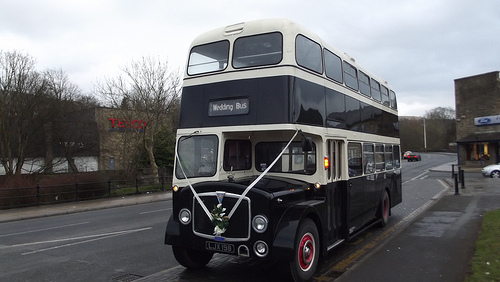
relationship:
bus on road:
[165, 17, 403, 281] [1, 151, 458, 280]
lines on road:
[0, 153, 450, 277] [1, 151, 458, 280]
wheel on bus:
[278, 216, 320, 281] [165, 17, 403, 281]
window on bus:
[232, 31, 282, 69] [165, 17, 403, 281]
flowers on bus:
[211, 203, 229, 239] [165, 17, 403, 281]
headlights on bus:
[179, 209, 267, 232] [165, 17, 403, 281]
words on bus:
[212, 102, 248, 110] [165, 17, 403, 281]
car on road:
[406, 152, 422, 163] [1, 151, 458, 280]